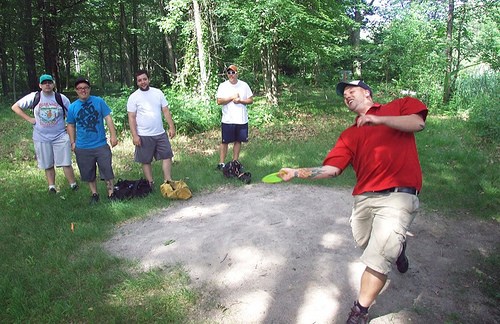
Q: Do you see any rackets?
A: No, there are no rackets.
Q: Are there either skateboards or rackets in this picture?
A: No, there are no rackets or skateboards.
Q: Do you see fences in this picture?
A: No, there are no fences.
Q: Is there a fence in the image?
A: No, there are no fences.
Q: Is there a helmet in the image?
A: No, there are no helmets.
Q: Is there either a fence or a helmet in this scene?
A: No, there are no helmets or fences.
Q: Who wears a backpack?
A: The man wears a backpack.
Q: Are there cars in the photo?
A: No, there are no cars.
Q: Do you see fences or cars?
A: No, there are no cars or fences.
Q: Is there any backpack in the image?
A: Yes, there is a backpack.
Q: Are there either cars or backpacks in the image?
A: Yes, there is a backpack.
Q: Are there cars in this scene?
A: No, there are no cars.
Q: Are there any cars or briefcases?
A: No, there are no cars or briefcases.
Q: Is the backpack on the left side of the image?
A: Yes, the backpack is on the left of the image.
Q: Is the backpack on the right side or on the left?
A: The backpack is on the left of the image.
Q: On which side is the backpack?
A: The backpack is on the left of the image.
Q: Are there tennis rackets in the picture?
A: No, there are no tennis rackets.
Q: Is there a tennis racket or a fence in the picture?
A: No, there are no rackets or fences.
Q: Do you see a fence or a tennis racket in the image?
A: No, there are no rackets or fences.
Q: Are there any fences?
A: No, there are no fences.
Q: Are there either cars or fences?
A: No, there are no fences or cars.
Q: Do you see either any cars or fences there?
A: No, there are no fences or cars.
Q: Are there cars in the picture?
A: No, there are no cars.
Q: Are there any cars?
A: No, there are no cars.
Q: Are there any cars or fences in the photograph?
A: No, there are no cars or fences.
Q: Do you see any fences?
A: No, there are no fences.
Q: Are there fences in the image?
A: No, there are no fences.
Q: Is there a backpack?
A: Yes, there is a backpack.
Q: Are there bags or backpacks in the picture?
A: Yes, there is a backpack.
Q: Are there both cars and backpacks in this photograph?
A: No, there is a backpack but no cars.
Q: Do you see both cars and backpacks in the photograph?
A: No, there is a backpack but no cars.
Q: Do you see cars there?
A: No, there are no cars.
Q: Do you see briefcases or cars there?
A: No, there are no cars or briefcases.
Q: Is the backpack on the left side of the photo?
A: Yes, the backpack is on the left of the image.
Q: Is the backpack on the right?
A: No, the backpack is on the left of the image.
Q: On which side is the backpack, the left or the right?
A: The backpack is on the left of the image.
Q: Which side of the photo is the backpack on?
A: The backpack is on the left of the image.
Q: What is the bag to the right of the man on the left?
A: The bag is a backpack.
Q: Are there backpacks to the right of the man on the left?
A: Yes, there is a backpack to the right of the man.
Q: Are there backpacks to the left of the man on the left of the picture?
A: No, the backpack is to the right of the man.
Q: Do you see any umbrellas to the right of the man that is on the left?
A: No, there is a backpack to the right of the man.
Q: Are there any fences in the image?
A: No, there are no fences.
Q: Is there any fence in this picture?
A: No, there are no fences.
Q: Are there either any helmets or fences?
A: No, there are no fences or helmets.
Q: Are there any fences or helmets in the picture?
A: No, there are no fences or helmets.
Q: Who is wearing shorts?
A: The man is wearing shorts.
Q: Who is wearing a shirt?
A: The man is wearing a shirt.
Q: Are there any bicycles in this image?
A: No, there are no bicycles.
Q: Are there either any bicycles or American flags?
A: No, there are no bicycles or American flags.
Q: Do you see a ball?
A: No, there are no balls.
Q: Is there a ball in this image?
A: No, there are no balls.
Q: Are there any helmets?
A: No, there are no helmets.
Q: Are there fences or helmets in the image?
A: No, there are no helmets or fences.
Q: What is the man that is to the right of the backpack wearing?
A: The man is wearing a shirt.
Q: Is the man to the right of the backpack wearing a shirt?
A: Yes, the man is wearing a shirt.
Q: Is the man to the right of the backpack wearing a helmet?
A: No, the man is wearing a shirt.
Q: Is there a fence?
A: No, there are no fences.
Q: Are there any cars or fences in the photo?
A: No, there are no fences or cars.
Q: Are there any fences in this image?
A: No, there are no fences.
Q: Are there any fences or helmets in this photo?
A: No, there are no fences or helmets.